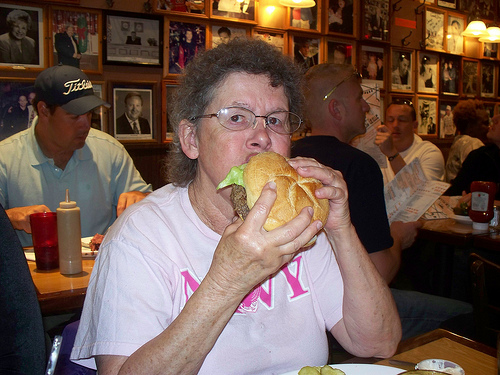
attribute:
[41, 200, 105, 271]
bottle — plastic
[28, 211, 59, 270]
red cup — translucent, plastic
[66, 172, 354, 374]
shirt —  short sleeved, white, pink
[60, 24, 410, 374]
woman — older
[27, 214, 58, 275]
cup — red, plastic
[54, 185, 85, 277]
bottle — beige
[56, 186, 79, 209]
lid — pointed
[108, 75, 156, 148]
photograph — framed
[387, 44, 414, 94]
photograph — framed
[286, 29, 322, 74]
photograph — framed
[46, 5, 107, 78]
photograph — framed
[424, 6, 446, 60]
photograph — framed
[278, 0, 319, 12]
light — small, yellow, dish-shaped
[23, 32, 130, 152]
cap — navy blue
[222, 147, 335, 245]
hamburger — giant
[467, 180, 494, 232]
ketchup bottle — squeezable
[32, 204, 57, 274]
glass — half-full, plastic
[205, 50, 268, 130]
hair — grey, frizzy